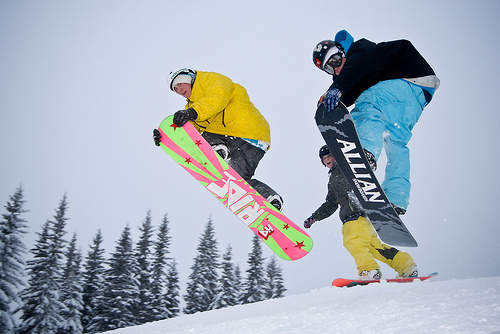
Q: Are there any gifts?
A: No, there are no gifts.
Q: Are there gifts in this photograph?
A: No, there are no gifts.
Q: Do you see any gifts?
A: No, there are no gifts.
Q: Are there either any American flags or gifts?
A: No, there are no gifts or American flags.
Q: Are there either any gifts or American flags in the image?
A: No, there are no gifts or American flags.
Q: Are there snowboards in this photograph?
A: Yes, there is a snowboard.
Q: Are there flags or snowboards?
A: Yes, there is a snowboard.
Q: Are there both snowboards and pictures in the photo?
A: No, there is a snowboard but no pictures.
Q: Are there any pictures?
A: No, there are no pictures.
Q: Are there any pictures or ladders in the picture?
A: No, there are no pictures or ladders.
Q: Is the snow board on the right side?
A: Yes, the snow board is on the right of the image.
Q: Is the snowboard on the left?
A: No, the snowboard is on the right of the image.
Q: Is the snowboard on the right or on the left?
A: The snowboard is on the right of the image.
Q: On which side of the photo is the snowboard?
A: The snowboard is on the right of the image.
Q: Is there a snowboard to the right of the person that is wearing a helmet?
A: Yes, there is a snowboard to the right of the person.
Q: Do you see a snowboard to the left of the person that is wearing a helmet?
A: No, the snowboard is to the right of the person.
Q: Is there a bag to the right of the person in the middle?
A: No, there is a snowboard to the right of the person.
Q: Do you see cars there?
A: No, there are no cars.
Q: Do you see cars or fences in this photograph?
A: No, there are no cars or fences.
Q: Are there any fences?
A: No, there are no fences.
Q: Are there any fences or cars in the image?
A: No, there are no fences or cars.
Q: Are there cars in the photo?
A: No, there are no cars.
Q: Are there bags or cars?
A: No, there are no cars or bags.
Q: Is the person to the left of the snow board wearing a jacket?
A: Yes, the person is wearing a jacket.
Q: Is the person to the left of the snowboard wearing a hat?
A: No, the person is wearing a jacket.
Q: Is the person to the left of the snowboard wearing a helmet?
A: Yes, the person is wearing a helmet.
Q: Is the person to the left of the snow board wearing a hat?
A: No, the person is wearing a helmet.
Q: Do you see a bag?
A: No, there are no bags.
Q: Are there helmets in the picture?
A: Yes, there is a helmet.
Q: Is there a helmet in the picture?
A: Yes, there is a helmet.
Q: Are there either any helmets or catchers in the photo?
A: Yes, there is a helmet.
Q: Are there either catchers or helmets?
A: Yes, there is a helmet.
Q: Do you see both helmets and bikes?
A: No, there is a helmet but no bikes.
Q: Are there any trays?
A: No, there are no trays.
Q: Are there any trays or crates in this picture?
A: No, there are no trays or crates.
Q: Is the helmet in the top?
A: Yes, the helmet is in the top of the image.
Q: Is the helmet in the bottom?
A: No, the helmet is in the top of the image.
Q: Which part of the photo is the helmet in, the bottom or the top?
A: The helmet is in the top of the image.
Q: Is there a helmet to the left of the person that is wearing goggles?
A: Yes, there is a helmet to the left of the person.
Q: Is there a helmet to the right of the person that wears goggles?
A: No, the helmet is to the left of the person.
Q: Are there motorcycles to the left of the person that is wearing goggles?
A: No, there is a helmet to the left of the person.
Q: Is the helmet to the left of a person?
A: Yes, the helmet is to the left of a person.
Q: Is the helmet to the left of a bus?
A: No, the helmet is to the left of a person.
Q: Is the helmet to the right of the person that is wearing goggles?
A: No, the helmet is to the left of the person.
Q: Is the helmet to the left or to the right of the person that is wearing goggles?
A: The helmet is to the left of the person.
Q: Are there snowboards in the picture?
A: Yes, there is a snowboard.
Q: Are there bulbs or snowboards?
A: Yes, there is a snowboard.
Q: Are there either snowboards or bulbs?
A: Yes, there is a snowboard.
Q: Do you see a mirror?
A: No, there are no mirrors.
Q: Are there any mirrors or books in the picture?
A: No, there are no mirrors or books.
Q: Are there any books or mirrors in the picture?
A: No, there are no mirrors or books.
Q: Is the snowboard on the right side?
A: Yes, the snowboard is on the right of the image.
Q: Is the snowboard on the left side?
A: No, the snowboard is on the right of the image.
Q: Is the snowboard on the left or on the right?
A: The snowboard is on the right of the image.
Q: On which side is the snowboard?
A: The snowboard is on the right of the image.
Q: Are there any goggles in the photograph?
A: Yes, there are goggles.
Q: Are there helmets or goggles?
A: Yes, there are goggles.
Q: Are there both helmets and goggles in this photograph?
A: Yes, there are both goggles and a helmet.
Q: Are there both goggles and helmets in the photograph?
A: Yes, there are both goggles and a helmet.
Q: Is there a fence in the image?
A: No, there are no fences.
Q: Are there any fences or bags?
A: No, there are no fences or bags.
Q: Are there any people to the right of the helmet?
A: Yes, there is a person to the right of the helmet.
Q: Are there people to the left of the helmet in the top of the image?
A: No, the person is to the right of the helmet.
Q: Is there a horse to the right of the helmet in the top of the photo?
A: No, there is a person to the right of the helmet.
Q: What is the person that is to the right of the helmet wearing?
A: The person is wearing goggles.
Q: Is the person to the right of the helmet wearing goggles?
A: Yes, the person is wearing goggles.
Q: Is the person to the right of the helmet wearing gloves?
A: No, the person is wearing goggles.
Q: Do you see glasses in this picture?
A: No, there are no glasses.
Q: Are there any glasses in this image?
A: No, there are no glasses.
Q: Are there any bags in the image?
A: No, there are no bags.